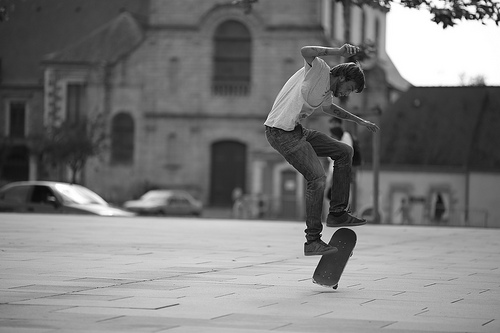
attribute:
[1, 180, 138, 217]
car — parked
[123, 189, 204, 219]
car — parked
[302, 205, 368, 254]
tennis shoes — dark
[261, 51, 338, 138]
shirt — white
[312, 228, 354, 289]
skateboard — flat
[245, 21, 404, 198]
shirt — white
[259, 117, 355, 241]
jeans — blue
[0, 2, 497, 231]
building — large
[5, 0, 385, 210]
building — large